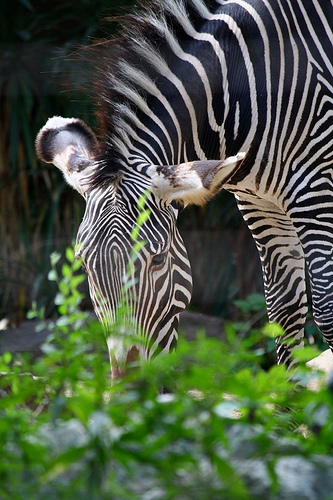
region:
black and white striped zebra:
[35, 15, 322, 352]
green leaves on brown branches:
[143, 397, 170, 415]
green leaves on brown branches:
[54, 438, 93, 469]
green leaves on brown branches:
[254, 406, 302, 437]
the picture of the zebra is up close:
[4, 15, 329, 435]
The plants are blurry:
[5, 284, 322, 499]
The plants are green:
[8, 353, 325, 498]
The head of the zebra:
[60, 187, 188, 391]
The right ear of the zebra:
[168, 146, 252, 223]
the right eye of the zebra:
[146, 245, 171, 267]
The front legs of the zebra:
[240, 202, 331, 435]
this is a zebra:
[37, 0, 331, 387]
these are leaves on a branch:
[47, 252, 86, 325]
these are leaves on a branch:
[186, 393, 235, 486]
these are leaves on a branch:
[173, 352, 248, 417]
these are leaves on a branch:
[129, 424, 196, 496]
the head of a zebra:
[33, 112, 263, 377]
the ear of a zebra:
[154, 146, 252, 224]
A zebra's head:
[75, 223, 190, 367]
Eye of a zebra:
[146, 249, 177, 268]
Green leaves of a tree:
[140, 373, 240, 426]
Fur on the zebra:
[78, 44, 149, 126]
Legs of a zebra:
[257, 217, 331, 328]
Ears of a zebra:
[40, 115, 233, 209]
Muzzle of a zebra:
[99, 344, 174, 413]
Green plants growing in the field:
[61, 353, 111, 439]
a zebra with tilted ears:
[34, 11, 331, 387]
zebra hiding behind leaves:
[32, 3, 331, 404]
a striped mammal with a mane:
[34, 3, 331, 374]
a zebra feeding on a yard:
[35, 5, 331, 407]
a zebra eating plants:
[2, 1, 332, 404]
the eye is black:
[143, 248, 171, 273]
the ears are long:
[25, 105, 252, 209]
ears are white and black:
[27, 111, 249, 217]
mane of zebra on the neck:
[73, 4, 211, 153]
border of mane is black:
[74, 1, 193, 141]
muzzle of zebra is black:
[93, 343, 165, 435]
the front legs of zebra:
[244, 213, 332, 375]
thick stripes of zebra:
[186, 28, 275, 118]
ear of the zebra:
[29, 118, 110, 208]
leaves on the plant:
[56, 356, 244, 461]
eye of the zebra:
[126, 222, 177, 293]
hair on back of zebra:
[79, 36, 168, 142]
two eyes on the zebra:
[62, 212, 198, 303]